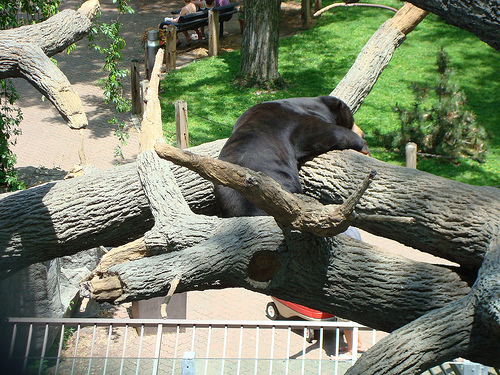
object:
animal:
[213, 93, 367, 223]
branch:
[1, 130, 500, 283]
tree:
[232, 0, 287, 92]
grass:
[290, 45, 324, 70]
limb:
[133, 46, 196, 228]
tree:
[0, 0, 499, 374]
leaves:
[413, 102, 431, 124]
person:
[158, 0, 198, 46]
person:
[193, 1, 217, 44]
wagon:
[264, 293, 339, 343]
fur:
[215, 94, 366, 220]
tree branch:
[0, 0, 106, 130]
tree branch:
[323, 0, 426, 116]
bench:
[156, 4, 238, 47]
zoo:
[0, 0, 500, 375]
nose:
[350, 122, 366, 140]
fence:
[8, 313, 500, 374]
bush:
[380, 43, 488, 167]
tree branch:
[0, 135, 499, 272]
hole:
[245, 246, 285, 283]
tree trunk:
[79, 215, 480, 337]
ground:
[0, 0, 500, 361]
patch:
[276, 21, 363, 68]